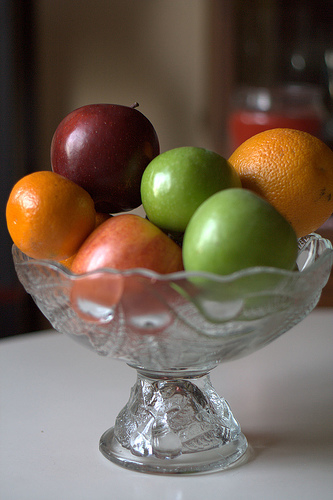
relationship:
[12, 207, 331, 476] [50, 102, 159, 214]
dish full of apple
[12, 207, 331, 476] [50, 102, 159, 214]
dish of apple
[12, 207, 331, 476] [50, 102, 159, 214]
dish with apple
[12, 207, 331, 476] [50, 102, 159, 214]
dish filled with apple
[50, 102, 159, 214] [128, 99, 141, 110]
apple with stem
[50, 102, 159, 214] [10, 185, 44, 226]
apple has reflection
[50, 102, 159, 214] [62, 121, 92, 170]
apple has reflection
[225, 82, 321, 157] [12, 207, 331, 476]
candle behind dish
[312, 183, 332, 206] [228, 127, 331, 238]
spot on orange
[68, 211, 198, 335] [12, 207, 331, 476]
apple inside of dish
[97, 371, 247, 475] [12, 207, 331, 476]
bottom of dish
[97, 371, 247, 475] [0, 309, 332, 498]
bottom on top of table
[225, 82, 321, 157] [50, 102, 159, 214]
candle behind apple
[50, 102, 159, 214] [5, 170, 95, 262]
apple on top of tangerine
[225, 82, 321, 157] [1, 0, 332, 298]
candle in background